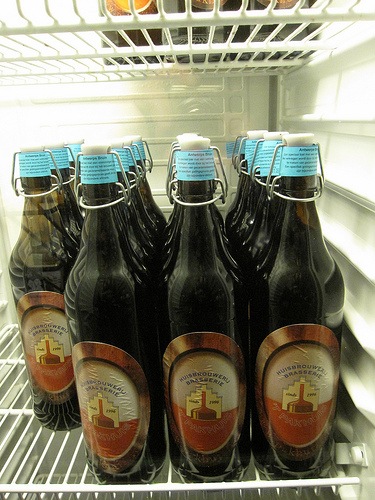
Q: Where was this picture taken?
A: In the refrigerator.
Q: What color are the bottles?
A: Brown.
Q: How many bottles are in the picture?
A: Fifteen.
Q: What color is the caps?
A: White.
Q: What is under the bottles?
A: A rack.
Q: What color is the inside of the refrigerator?
A: White.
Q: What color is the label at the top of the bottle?
A: Blue.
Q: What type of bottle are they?
A: Glass.